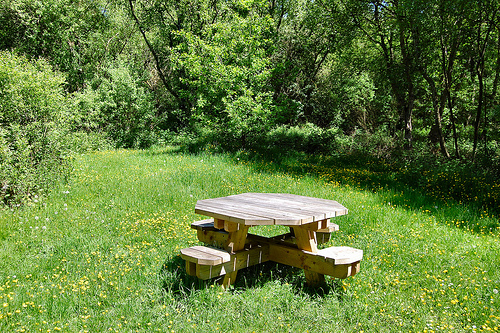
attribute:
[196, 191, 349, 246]
table — wood, wooden, octagon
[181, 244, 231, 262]
chair — in photo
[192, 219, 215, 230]
chair — wood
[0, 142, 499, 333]
grass — green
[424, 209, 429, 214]
flower — yellow, in grass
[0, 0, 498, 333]
photo — without person, animal free, without people, without birds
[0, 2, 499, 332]
daytime — sunny